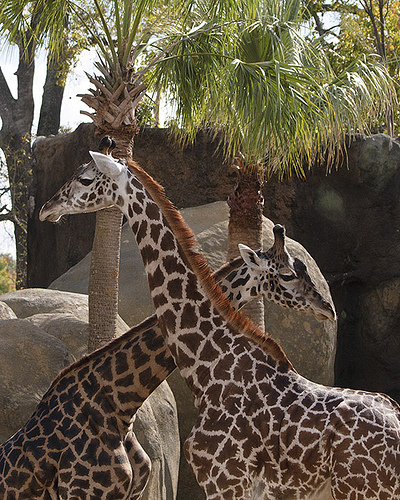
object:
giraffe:
[37, 133, 400, 500]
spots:
[180, 302, 198, 329]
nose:
[39, 200, 52, 221]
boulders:
[291, 133, 400, 391]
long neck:
[119, 156, 231, 387]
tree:
[144, 0, 399, 329]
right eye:
[279, 274, 294, 281]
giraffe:
[0, 223, 337, 500]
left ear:
[89, 150, 123, 177]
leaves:
[278, 51, 396, 171]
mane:
[126, 159, 297, 375]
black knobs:
[102, 136, 116, 150]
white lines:
[270, 399, 382, 459]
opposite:
[36, 132, 341, 333]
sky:
[5, 15, 391, 135]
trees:
[299, 0, 396, 138]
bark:
[225, 155, 264, 259]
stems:
[299, 58, 370, 116]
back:
[291, 372, 399, 434]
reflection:
[288, 368, 400, 427]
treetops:
[83, 68, 128, 130]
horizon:
[10, 86, 398, 139]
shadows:
[36, 121, 390, 179]